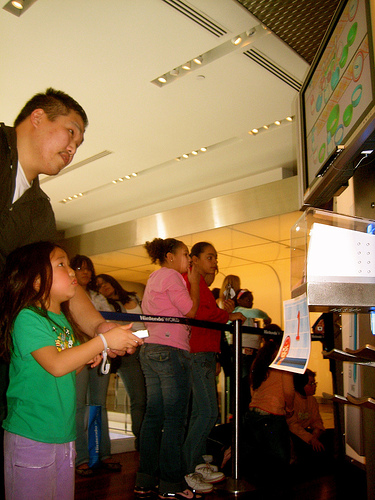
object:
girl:
[134, 238, 199, 499]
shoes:
[132, 483, 203, 499]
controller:
[132, 329, 149, 343]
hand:
[101, 323, 144, 354]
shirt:
[0, 298, 84, 446]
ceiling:
[69, 29, 125, 76]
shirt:
[140, 267, 194, 353]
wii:
[96, 332, 111, 375]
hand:
[94, 322, 144, 358]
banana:
[137, 232, 187, 352]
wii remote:
[132, 329, 150, 343]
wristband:
[99, 332, 110, 374]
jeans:
[140, 340, 192, 495]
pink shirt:
[140, 268, 192, 352]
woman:
[133, 237, 201, 499]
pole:
[225, 318, 246, 495]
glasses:
[306, 381, 319, 387]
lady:
[288, 366, 348, 498]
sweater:
[285, 391, 325, 444]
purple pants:
[4, 429, 75, 499]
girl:
[0, 240, 145, 500]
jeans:
[183, 349, 219, 475]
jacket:
[181, 266, 230, 354]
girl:
[180, 241, 243, 495]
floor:
[67, 436, 334, 499]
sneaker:
[161, 488, 199, 498]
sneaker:
[131, 481, 159, 497]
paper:
[269, 292, 312, 374]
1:
[296, 310, 301, 340]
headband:
[237, 289, 246, 300]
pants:
[4, 427, 77, 500]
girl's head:
[18, 239, 78, 309]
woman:
[52, 254, 116, 498]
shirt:
[79, 287, 116, 325]